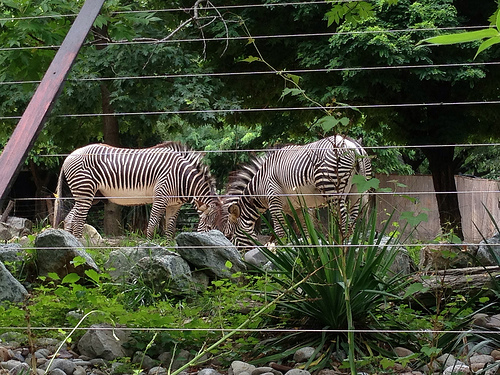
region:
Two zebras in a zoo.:
[46, 108, 389, 273]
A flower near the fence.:
[260, 186, 422, 363]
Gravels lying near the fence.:
[8, 330, 498, 372]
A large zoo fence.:
[6, 3, 498, 366]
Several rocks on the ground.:
[118, 216, 256, 300]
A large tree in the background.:
[369, 75, 498, 256]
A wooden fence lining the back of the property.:
[383, 155, 498, 230]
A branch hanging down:
[106, 3, 311, 104]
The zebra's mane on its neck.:
[153, 138, 223, 188]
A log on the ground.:
[417, 264, 499, 299]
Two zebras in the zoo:
[57, 119, 398, 253]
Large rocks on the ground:
[162, 219, 279, 295]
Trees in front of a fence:
[403, 151, 473, 317]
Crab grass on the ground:
[259, 214, 404, 352]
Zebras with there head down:
[191, 146, 264, 251]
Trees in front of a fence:
[407, 78, 484, 290]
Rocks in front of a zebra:
[139, 222, 262, 284]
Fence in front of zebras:
[129, 19, 467, 345]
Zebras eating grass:
[189, 154, 285, 252]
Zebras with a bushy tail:
[338, 141, 391, 220]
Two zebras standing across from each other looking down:
[52, 142, 369, 253]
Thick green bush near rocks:
[240, 204, 397, 336]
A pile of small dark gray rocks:
[24, 326, 134, 367]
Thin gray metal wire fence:
[113, 46, 439, 152]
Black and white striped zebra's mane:
[175, 143, 227, 174]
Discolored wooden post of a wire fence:
[0, 0, 70, 150]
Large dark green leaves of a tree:
[111, 20, 207, 106]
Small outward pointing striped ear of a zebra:
[190, 197, 205, 212]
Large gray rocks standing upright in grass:
[49, 226, 243, 293]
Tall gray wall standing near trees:
[380, 161, 437, 240]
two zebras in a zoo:
[2, 80, 499, 302]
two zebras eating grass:
[51, 125, 398, 262]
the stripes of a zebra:
[88, 150, 179, 192]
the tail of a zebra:
[43, 164, 68, 231]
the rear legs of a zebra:
[63, 192, 98, 239]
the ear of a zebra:
[225, 202, 241, 219]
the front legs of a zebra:
[140, 196, 181, 241]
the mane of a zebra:
[216, 147, 268, 201]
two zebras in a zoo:
[26, 62, 403, 272]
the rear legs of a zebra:
[64, 186, 97, 244]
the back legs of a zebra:
[59, 191, 94, 238]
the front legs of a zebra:
[137, 188, 187, 244]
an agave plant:
[238, 173, 425, 335]